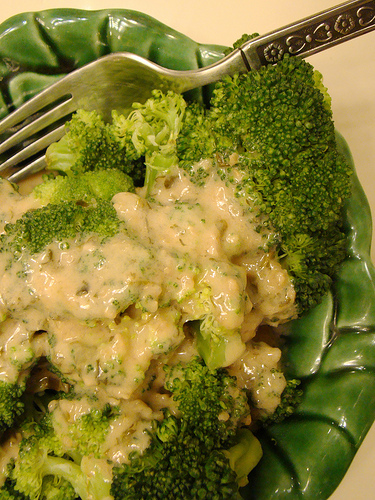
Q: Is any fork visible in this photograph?
A: Yes, there is a fork.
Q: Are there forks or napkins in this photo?
A: Yes, there is a fork.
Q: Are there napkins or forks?
A: Yes, there is a fork.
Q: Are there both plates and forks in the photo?
A: Yes, there are both a fork and a plate.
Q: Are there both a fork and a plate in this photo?
A: Yes, there are both a fork and a plate.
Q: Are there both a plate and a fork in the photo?
A: Yes, there are both a fork and a plate.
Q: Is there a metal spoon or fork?
A: Yes, there is a metal fork.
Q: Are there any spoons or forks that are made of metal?
A: Yes, the fork is made of metal.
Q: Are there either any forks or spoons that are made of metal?
A: Yes, the fork is made of metal.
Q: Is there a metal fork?
A: Yes, there is a fork that is made of metal.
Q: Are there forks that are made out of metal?
A: Yes, there is a fork that is made of metal.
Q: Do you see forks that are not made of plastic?
A: Yes, there is a fork that is made of metal.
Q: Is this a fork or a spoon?
A: This is a fork.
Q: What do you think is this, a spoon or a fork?
A: This is a fork.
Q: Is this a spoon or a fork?
A: This is a fork.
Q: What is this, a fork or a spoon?
A: This is a fork.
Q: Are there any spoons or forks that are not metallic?
A: No, there is a fork but it is metallic.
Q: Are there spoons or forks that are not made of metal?
A: No, there is a fork but it is made of metal.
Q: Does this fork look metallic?
A: Yes, the fork is metallic.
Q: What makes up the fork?
A: The fork is made of metal.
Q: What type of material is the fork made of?
A: The fork is made of metal.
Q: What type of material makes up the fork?
A: The fork is made of metal.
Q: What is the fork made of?
A: The fork is made of metal.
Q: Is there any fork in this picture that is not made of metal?
A: No, there is a fork but it is made of metal.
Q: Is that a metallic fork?
A: Yes, that is a metallic fork.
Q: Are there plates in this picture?
A: Yes, there is a plate.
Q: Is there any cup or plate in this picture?
A: Yes, there is a plate.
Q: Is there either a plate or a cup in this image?
A: Yes, there is a plate.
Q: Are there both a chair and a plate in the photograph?
A: No, there is a plate but no chairs.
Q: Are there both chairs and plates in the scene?
A: No, there is a plate but no chairs.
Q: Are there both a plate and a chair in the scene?
A: No, there is a plate but no chairs.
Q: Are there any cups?
A: No, there are no cups.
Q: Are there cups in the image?
A: No, there are no cups.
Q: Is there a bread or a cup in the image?
A: No, there are no cups or breads.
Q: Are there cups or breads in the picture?
A: No, there are no cups or breads.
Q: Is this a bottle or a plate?
A: This is a plate.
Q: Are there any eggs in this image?
A: No, there are no eggs.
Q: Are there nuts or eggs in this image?
A: No, there are no eggs or nuts.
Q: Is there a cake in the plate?
A: No, there is a vegetable in the plate.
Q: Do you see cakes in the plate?
A: No, there is a vegetable in the plate.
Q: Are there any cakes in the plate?
A: No, there is a vegetable in the plate.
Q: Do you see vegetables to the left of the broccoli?
A: Yes, there is a vegetable to the left of the broccoli.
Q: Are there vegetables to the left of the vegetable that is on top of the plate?
A: Yes, there is a vegetable to the left of the broccoli.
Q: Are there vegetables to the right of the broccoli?
A: No, the vegetable is to the left of the broccoli.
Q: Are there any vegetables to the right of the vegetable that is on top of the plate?
A: No, the vegetable is to the left of the broccoli.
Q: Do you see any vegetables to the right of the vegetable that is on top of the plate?
A: No, the vegetable is to the left of the broccoli.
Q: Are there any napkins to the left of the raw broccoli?
A: No, there is a vegetable to the left of the broccoli.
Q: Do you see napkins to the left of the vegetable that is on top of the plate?
A: No, there is a vegetable to the left of the broccoli.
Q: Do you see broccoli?
A: Yes, there is broccoli.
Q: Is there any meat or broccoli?
A: Yes, there is broccoli.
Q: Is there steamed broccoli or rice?
A: Yes, there is steamed broccoli.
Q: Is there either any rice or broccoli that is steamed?
A: Yes, the broccoli is steamed.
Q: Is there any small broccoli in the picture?
A: Yes, there is small broccoli.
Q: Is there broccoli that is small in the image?
A: Yes, there is small broccoli.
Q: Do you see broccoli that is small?
A: Yes, there is small broccoli.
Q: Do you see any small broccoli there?
A: Yes, there is small broccoli.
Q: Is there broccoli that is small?
A: Yes, there is broccoli that is small.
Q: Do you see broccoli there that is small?
A: Yes, there is broccoli that is small.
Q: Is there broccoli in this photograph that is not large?
A: Yes, there is small broccoli.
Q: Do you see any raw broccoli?
A: Yes, there is raw broccoli.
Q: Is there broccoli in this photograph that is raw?
A: Yes, there is broccoli that is raw.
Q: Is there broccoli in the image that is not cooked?
A: Yes, there is raw broccoli.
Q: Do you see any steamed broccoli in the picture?
A: Yes, there is steamed broccoli.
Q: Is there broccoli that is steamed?
A: Yes, there is broccoli that is steamed.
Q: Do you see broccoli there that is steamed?
A: Yes, there is broccoli that is steamed.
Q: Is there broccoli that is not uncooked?
A: Yes, there is steamed broccoli.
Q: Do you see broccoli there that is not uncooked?
A: Yes, there is steamed broccoli.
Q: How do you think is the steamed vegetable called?
A: The vegetable is broccoli.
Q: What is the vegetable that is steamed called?
A: The vegetable is broccoli.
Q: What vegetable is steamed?
A: The vegetable is broccoli.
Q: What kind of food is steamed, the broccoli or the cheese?
A: The broccoli is steamed.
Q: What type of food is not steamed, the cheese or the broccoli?
A: The cheese is not steamed.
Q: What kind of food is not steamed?
A: The food is cheese.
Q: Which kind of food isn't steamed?
A: The food is cheese.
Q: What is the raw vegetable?
A: The vegetable is broccoli.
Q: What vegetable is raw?
A: The vegetable is broccoli.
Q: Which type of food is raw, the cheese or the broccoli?
A: The broccoli is raw.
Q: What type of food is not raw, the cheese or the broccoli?
A: The cheese is not raw.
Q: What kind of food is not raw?
A: The food is cheese.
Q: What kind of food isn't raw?
A: The food is cheese.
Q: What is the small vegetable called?
A: The vegetable is broccoli.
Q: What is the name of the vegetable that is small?
A: The vegetable is broccoli.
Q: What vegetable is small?
A: The vegetable is broccoli.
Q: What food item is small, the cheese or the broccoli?
A: The broccoli is small.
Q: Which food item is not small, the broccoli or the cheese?
A: The cheese is not small.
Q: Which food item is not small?
A: The food item is cheese.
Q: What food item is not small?
A: The food item is cheese.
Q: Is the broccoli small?
A: Yes, the broccoli is small.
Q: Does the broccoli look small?
A: Yes, the broccoli is small.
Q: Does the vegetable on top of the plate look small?
A: Yes, the broccoli is small.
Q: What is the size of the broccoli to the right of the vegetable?
A: The broccoli is small.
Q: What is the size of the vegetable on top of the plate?
A: The broccoli is small.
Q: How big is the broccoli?
A: The broccoli is small.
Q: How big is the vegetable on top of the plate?
A: The broccoli is small.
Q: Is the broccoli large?
A: No, the broccoli is small.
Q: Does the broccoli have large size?
A: No, the broccoli is small.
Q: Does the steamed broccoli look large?
A: No, the broccoli is small.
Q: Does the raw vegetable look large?
A: No, the broccoli is small.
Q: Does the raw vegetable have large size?
A: No, the broccoli is small.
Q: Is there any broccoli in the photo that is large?
A: No, there is broccoli but it is small.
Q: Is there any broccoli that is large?
A: No, there is broccoli but it is small.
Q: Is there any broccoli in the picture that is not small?
A: No, there is broccoli but it is small.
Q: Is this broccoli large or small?
A: The broccoli is small.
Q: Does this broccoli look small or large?
A: The broccoli is small.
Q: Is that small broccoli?
A: Yes, that is small broccoli.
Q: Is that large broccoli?
A: No, that is small broccoli.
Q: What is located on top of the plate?
A: The broccoli is on top of the plate.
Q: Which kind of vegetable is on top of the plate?
A: The vegetable is broccoli.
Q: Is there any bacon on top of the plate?
A: No, there is broccoli on top of the plate.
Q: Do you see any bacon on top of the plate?
A: No, there is broccoli on top of the plate.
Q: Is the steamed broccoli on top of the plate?
A: Yes, the broccoli is on top of the plate.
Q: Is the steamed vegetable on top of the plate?
A: Yes, the broccoli is on top of the plate.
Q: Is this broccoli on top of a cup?
A: No, the broccoli is on top of the plate.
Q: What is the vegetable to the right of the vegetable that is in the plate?
A: The vegetable is broccoli.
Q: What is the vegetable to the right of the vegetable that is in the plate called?
A: The vegetable is broccoli.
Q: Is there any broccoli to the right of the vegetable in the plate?
A: Yes, there is broccoli to the right of the vegetable.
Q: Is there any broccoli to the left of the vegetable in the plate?
A: No, the broccoli is to the right of the vegetable.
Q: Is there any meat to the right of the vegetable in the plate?
A: No, there is broccoli to the right of the vegetable.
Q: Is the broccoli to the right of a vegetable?
A: Yes, the broccoli is to the right of a vegetable.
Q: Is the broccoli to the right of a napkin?
A: No, the broccoli is to the right of a vegetable.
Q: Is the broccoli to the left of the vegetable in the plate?
A: No, the broccoli is to the right of the vegetable.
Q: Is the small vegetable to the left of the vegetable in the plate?
A: No, the broccoli is to the right of the vegetable.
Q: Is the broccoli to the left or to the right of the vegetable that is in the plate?
A: The broccoli is to the right of the vegetable.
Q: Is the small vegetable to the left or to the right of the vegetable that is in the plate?
A: The broccoli is to the right of the vegetable.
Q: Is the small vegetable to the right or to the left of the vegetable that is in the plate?
A: The broccoli is to the right of the vegetable.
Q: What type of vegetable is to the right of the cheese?
A: The vegetable is broccoli.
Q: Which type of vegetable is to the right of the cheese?
A: The vegetable is broccoli.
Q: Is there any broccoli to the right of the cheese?
A: Yes, there is broccoli to the right of the cheese.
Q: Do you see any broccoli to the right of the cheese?
A: Yes, there is broccoli to the right of the cheese.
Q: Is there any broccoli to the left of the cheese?
A: No, the broccoli is to the right of the cheese.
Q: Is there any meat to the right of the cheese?
A: No, there is broccoli to the right of the cheese.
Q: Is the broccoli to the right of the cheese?
A: Yes, the broccoli is to the right of the cheese.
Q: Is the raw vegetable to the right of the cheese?
A: Yes, the broccoli is to the right of the cheese.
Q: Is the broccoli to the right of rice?
A: No, the broccoli is to the right of the cheese.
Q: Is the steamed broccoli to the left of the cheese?
A: No, the broccoli is to the right of the cheese.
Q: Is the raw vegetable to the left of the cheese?
A: No, the broccoli is to the right of the cheese.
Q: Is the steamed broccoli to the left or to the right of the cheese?
A: The broccoli is to the right of the cheese.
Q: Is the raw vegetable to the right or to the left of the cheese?
A: The broccoli is to the right of the cheese.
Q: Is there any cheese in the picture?
A: Yes, there is cheese.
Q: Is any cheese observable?
A: Yes, there is cheese.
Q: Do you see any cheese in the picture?
A: Yes, there is cheese.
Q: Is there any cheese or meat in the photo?
A: Yes, there is cheese.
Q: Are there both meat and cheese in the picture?
A: No, there is cheese but no meat.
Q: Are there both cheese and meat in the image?
A: No, there is cheese but no meat.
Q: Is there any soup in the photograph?
A: No, there is no soup.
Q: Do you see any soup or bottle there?
A: No, there are no soup or bottles.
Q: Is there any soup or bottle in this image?
A: No, there are no soup or bottles.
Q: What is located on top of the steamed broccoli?
A: The cheese is on top of the broccoli.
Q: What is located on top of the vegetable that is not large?
A: The cheese is on top of the broccoli.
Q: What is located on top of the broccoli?
A: The cheese is on top of the broccoli.